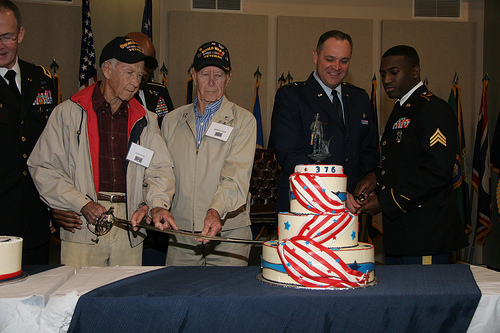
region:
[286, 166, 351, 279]
a heap of cakes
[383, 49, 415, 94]
the head of a man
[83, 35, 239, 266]
two old me holding a sword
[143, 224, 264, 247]
a sword for cutting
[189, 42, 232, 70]
a cap on the head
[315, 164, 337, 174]
number 376 on the top of a cake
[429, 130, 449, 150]
a badge of the uniform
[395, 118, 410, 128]
medals on the uniform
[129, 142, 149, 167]
a tag on a jacket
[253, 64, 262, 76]
the tip of a flag pole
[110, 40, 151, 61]
hat on the person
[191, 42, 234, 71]
hat on the person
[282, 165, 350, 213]
layer of the cake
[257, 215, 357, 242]
layer of the cake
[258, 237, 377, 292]
layer of the cake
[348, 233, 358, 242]
star on the cake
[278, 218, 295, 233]
star on the cake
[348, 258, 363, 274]
star on the cake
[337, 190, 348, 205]
star on the cake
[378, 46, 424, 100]
The man's hair is black.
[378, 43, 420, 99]
The man's hair is short.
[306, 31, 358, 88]
The man's hair is brown.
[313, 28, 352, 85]
The man's hair is short.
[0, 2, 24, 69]
The man is wearing glasses.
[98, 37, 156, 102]
The man is wearing a hat.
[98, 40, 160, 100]
The man's hair is grey.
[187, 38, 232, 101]
The man is wearing a hat.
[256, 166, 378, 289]
The cake is three layers.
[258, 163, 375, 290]
The cake is red, white and blue.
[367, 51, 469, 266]
A man near a cake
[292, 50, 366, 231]
A man near a cake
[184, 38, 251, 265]
A man near a cake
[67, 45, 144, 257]
A man near a cake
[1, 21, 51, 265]
A man near a cake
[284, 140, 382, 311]
A delicious looking cake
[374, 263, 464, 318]
A blue table cloth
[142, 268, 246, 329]
A blue table cloth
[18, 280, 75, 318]
A white table cloth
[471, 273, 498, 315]
A white table cloth